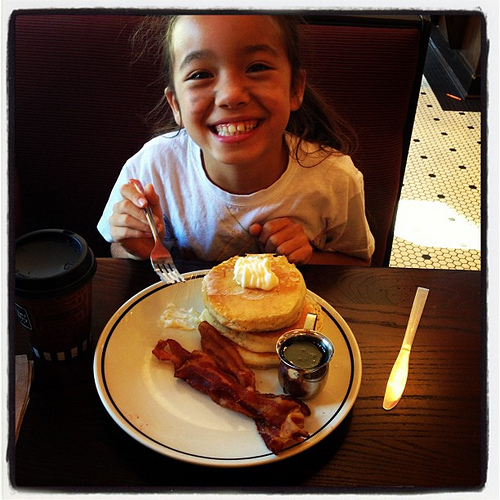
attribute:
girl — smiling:
[85, 15, 385, 257]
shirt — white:
[182, 186, 213, 222]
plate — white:
[146, 276, 188, 294]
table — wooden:
[370, 450, 438, 484]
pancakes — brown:
[202, 251, 315, 333]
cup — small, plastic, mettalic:
[276, 327, 340, 390]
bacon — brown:
[159, 331, 242, 393]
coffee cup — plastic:
[19, 223, 94, 363]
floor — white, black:
[420, 140, 465, 185]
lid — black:
[20, 223, 88, 285]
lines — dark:
[349, 299, 396, 328]